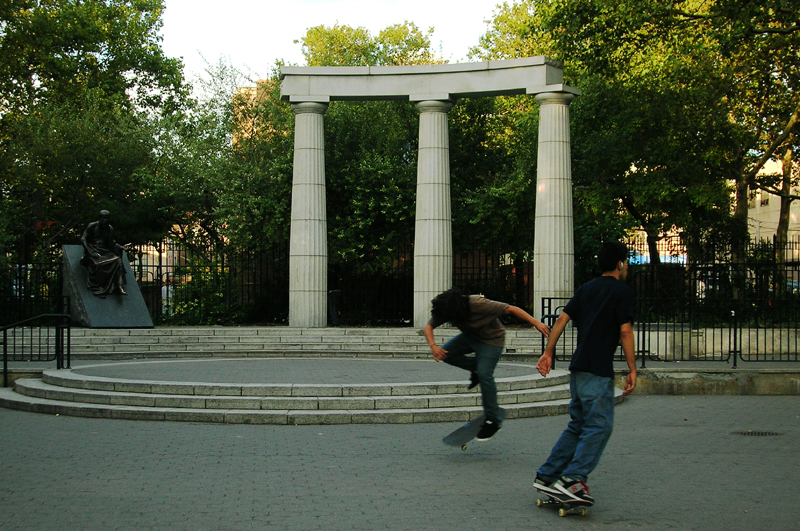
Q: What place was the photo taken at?
A: It was taken at the city.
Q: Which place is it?
A: It is a city.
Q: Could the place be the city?
A: Yes, it is the city.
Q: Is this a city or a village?
A: It is a city.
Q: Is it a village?
A: No, it is a city.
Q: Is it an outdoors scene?
A: Yes, it is outdoors.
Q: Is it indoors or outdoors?
A: It is outdoors.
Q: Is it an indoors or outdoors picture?
A: It is outdoors.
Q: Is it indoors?
A: No, it is outdoors.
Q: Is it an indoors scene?
A: No, it is outdoors.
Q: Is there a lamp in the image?
A: No, there are no lamps.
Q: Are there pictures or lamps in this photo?
A: No, there are no lamps or pictures.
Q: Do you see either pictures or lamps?
A: No, there are no lamps or pictures.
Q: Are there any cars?
A: No, there are no cars.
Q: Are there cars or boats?
A: No, there are no cars or boats.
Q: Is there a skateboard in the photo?
A: Yes, there is a skateboard.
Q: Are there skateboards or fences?
A: Yes, there is a skateboard.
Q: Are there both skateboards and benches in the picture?
A: No, there is a skateboard but no benches.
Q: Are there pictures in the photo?
A: No, there are no pictures.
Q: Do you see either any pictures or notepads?
A: No, there are no pictures or notepads.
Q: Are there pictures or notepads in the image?
A: No, there are no pictures or notepads.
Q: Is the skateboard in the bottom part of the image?
A: Yes, the skateboard is in the bottom of the image.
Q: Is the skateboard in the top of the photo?
A: No, the skateboard is in the bottom of the image.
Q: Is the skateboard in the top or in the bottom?
A: The skateboard is in the bottom of the image.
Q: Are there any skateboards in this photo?
A: Yes, there is a skateboard.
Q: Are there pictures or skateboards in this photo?
A: Yes, there is a skateboard.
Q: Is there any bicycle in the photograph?
A: No, there are no bicycles.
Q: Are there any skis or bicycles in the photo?
A: No, there are no bicycles or skis.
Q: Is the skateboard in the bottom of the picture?
A: Yes, the skateboard is in the bottom of the image.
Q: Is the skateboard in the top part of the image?
A: No, the skateboard is in the bottom of the image.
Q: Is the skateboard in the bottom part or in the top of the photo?
A: The skateboard is in the bottom of the image.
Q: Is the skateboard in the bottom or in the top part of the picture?
A: The skateboard is in the bottom of the image.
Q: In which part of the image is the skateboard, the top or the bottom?
A: The skateboard is in the bottom of the image.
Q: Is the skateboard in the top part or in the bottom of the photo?
A: The skateboard is in the bottom of the image.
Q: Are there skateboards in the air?
A: Yes, there is a skateboard in the air.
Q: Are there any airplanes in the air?
A: No, there is a skateboard in the air.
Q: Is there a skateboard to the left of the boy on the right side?
A: Yes, there is a skateboard to the left of the boy.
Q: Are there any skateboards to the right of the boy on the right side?
A: No, the skateboard is to the left of the boy.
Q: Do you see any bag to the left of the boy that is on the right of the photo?
A: No, there is a skateboard to the left of the boy.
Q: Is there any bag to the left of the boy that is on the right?
A: No, there is a skateboard to the left of the boy.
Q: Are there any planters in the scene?
A: No, there are no planters.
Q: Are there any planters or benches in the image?
A: No, there are no planters or benches.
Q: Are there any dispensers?
A: No, there are no dispensers.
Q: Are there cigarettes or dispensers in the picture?
A: No, there are no dispensers or cigarettes.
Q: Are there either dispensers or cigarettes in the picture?
A: No, there are no dispensers or cigarettes.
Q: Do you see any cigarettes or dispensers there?
A: No, there are no dispensers or cigarettes.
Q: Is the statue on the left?
A: Yes, the statue is on the left of the image.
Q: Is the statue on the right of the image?
A: No, the statue is on the left of the image.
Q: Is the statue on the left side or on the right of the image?
A: The statue is on the left of the image.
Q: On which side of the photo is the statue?
A: The statue is on the left of the image.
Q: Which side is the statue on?
A: The statue is on the left of the image.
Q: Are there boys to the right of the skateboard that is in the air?
A: Yes, there is a boy to the right of the skateboard.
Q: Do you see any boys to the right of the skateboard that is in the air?
A: Yes, there is a boy to the right of the skateboard.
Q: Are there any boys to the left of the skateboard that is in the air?
A: No, the boy is to the right of the skateboard.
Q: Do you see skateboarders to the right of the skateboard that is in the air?
A: No, there is a boy to the right of the skateboard.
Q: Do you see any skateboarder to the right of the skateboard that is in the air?
A: No, there is a boy to the right of the skateboard.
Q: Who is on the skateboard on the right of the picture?
A: The boy is on the skateboard.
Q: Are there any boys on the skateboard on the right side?
A: Yes, there is a boy on the skateboard.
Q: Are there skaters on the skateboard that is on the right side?
A: No, there is a boy on the skateboard.